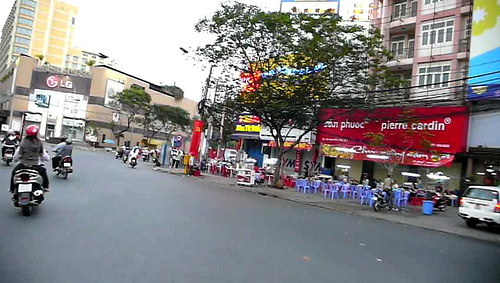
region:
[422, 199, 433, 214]
a bright blue trash can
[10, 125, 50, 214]
a person on motorcycle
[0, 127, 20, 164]
a person on motorcycle a person on motorcycle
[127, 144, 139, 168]
a person on motorcycle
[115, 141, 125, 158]
a person on motorcycle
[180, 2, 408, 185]
large green tree in distance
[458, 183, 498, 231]
a white SUV in driveway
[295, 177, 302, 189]
a plastic blue chair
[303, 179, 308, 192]
a plastic blue chair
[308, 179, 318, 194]
a plastic blue chair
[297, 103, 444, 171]
red and white sign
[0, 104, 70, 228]
girl is on bike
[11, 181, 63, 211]
white license plate on bike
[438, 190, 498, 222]
white van is parked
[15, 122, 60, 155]
girl has black helmet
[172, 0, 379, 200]
green tree near road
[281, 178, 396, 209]
blue and plastic chairs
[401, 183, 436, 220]
blue bin near road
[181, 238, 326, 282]
road is dark grey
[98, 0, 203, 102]
sky is grey and white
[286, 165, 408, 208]
seating on the sidewalk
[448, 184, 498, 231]
vehicle on the drive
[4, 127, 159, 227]
motorized bikes on the street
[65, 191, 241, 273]
street where vehicles travel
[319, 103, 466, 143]
covering over the storefron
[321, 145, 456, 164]
banner hanging from building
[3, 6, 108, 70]
building in the distance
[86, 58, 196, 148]
building on the street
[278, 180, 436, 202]
sidewalk in front of buildings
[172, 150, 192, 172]
pedestrians on the sidewalk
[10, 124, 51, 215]
Person riding motorcycle on road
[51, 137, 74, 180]
Person riding motorcycle on road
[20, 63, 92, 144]
Black and white LG store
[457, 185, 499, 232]
White SUV on sidewalk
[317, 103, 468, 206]
Red shopping store on sidewalk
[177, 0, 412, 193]
Large tree on sidewalk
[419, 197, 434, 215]
Blue trash can on sidewalk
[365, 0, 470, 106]
Large red brick building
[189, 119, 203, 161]
Red sign attached to pole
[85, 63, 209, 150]
Large brown building in background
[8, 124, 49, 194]
person with a red helmet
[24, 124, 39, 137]
helmet is red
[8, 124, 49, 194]
person on a motorcycle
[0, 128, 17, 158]
person on a motorcycle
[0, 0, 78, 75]
building is yellow and blue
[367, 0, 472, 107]
building is pink in color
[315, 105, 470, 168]
big sign is red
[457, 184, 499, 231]
white car is parked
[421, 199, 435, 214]
trash can is blue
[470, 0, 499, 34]
yellow flower on the building